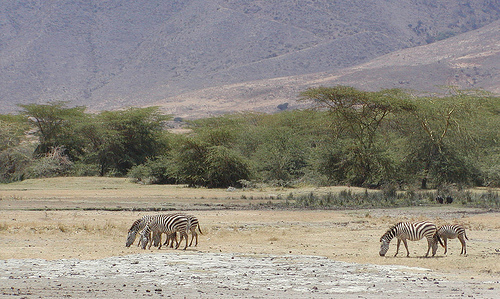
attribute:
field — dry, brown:
[10, 77, 491, 293]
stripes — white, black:
[415, 221, 430, 236]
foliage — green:
[296, 85, 418, 106]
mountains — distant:
[4, 2, 493, 116]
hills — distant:
[6, 7, 23, 11]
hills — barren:
[13, 7, 499, 118]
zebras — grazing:
[123, 210, 215, 249]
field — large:
[9, 181, 498, 292]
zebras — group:
[93, 137, 485, 289]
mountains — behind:
[1, 1, 499, 183]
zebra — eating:
[374, 220, 420, 256]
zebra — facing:
[429, 220, 471, 257]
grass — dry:
[30, 166, 487, 295]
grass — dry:
[272, 207, 313, 250]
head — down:
[138, 225, 152, 252]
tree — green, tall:
[295, 82, 419, 188]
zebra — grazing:
[119, 213, 194, 245]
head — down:
[124, 228, 136, 246]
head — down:
[376, 237, 390, 257]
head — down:
[136, 231, 149, 248]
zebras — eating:
[363, 203, 428, 252]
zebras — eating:
[377, 218, 467, 260]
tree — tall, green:
[302, 75, 430, 186]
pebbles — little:
[110, 256, 338, 285]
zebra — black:
[374, 219, 444, 261]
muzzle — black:
[376, 245, 388, 257]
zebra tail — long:
[460, 223, 467, 245]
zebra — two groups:
[381, 220, 435, 256]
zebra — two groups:
[431, 222, 466, 254]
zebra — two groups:
[126, 209, 175, 249]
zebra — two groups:
[141, 203, 188, 247]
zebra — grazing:
[380, 220, 445, 257]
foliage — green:
[2, 89, 497, 191]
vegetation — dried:
[15, 184, 475, 251]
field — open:
[5, 170, 482, 291]